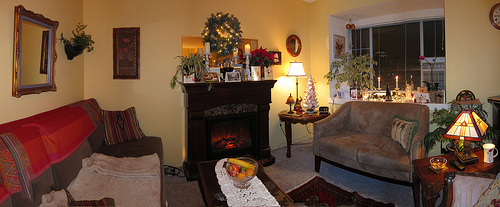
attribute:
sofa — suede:
[310, 99, 430, 194]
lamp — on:
[443, 107, 489, 166]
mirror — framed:
[18, 23, 53, 86]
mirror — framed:
[9, 30, 56, 95]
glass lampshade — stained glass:
[443, 106, 488, 141]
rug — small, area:
[290, 172, 411, 206]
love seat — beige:
[7, 102, 166, 204]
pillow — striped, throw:
[100, 106, 145, 145]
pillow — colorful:
[93, 103, 153, 153]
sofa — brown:
[307, 95, 436, 182]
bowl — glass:
[223, 149, 262, 188]